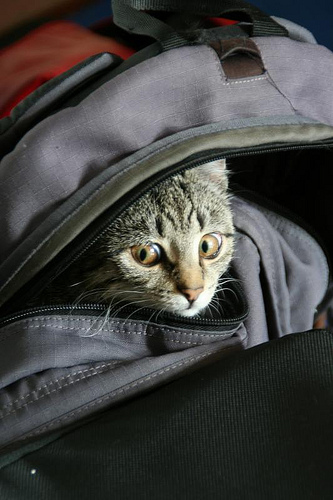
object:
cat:
[73, 158, 235, 318]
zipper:
[8, 241, 118, 336]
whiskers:
[73, 266, 176, 319]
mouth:
[173, 295, 207, 318]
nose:
[179, 286, 205, 302]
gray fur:
[171, 184, 205, 204]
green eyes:
[198, 235, 218, 258]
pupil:
[202, 239, 210, 253]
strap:
[108, 2, 289, 47]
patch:
[18, 30, 138, 73]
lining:
[254, 177, 331, 311]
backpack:
[12, 30, 330, 400]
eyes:
[130, 234, 222, 268]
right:
[48, 234, 67, 276]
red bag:
[6, 11, 149, 119]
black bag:
[0, 331, 330, 498]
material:
[101, 76, 246, 136]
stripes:
[159, 191, 207, 230]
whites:
[211, 229, 222, 247]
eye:
[198, 233, 221, 260]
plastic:
[67, 40, 79, 45]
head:
[156, 199, 209, 225]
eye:
[131, 240, 162, 266]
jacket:
[233, 189, 324, 285]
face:
[116, 201, 235, 305]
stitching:
[214, 57, 268, 84]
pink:
[180, 288, 202, 298]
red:
[25, 28, 101, 74]